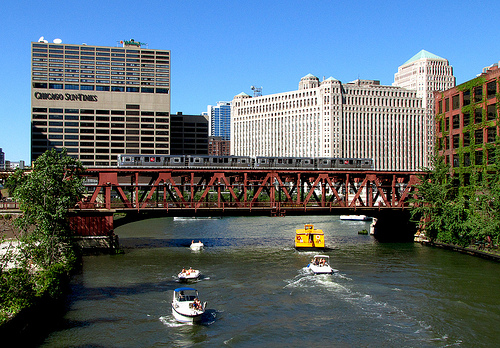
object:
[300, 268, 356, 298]
splash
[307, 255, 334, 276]
boat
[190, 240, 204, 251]
boat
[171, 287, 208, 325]
boat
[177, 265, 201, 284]
boat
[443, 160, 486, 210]
green vines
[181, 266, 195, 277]
people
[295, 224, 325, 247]
boat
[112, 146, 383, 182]
train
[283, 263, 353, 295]
wake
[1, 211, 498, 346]
river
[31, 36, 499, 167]
building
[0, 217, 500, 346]
water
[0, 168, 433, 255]
bridge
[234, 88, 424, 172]
windows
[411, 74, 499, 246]
ivy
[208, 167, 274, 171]
edge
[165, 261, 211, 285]
roof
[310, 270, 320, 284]
part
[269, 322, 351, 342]
part